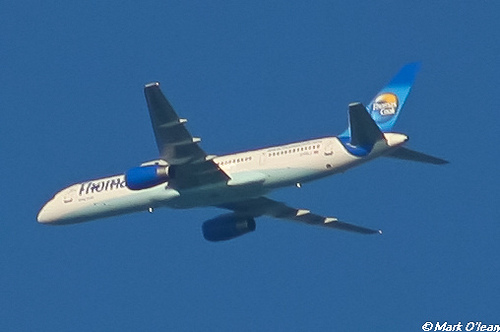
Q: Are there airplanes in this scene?
A: Yes, there is an airplane.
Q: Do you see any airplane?
A: Yes, there is an airplane.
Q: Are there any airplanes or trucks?
A: Yes, there is an airplane.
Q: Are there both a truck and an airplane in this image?
A: No, there is an airplane but no trucks.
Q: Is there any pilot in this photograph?
A: No, there are no pilots.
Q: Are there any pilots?
A: No, there are no pilots.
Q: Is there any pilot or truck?
A: No, there are no pilots or trucks.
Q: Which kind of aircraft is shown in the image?
A: The aircraft is an airplane.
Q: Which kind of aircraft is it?
A: The aircraft is an airplane.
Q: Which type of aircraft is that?
A: This is an airplane.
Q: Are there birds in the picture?
A: No, there are no birds.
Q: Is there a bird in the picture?
A: No, there are no birds.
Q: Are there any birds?
A: No, there are no birds.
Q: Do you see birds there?
A: No, there are no birds.